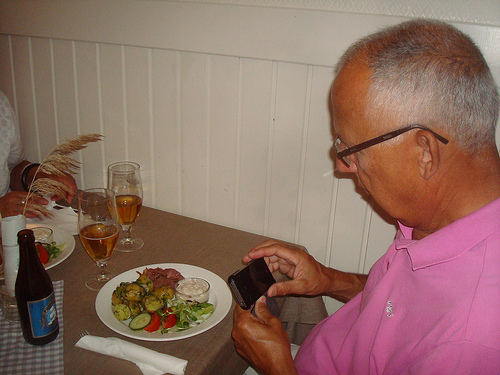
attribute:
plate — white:
[78, 255, 238, 345]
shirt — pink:
[290, 196, 498, 374]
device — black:
[226, 259, 278, 306]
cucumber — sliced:
[127, 312, 162, 329]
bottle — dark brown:
[14, 229, 60, 347]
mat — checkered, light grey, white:
[2, 276, 65, 373]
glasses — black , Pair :
[318, 130, 472, 202]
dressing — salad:
[175, 275, 212, 303]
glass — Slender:
[83, 185, 123, 291]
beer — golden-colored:
[77, 221, 119, 259]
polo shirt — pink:
[291, 195, 497, 372]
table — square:
[69, 173, 293, 374]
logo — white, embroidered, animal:
[384, 304, 395, 321]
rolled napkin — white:
[60, 338, 194, 373]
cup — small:
[172, 274, 212, 301]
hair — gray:
[331, 18, 499, 159]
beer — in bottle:
[13, 227, 61, 346]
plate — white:
[96, 261, 233, 343]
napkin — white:
[79, 335, 184, 374]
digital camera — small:
[229, 243, 276, 304]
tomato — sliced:
[159, 309, 175, 329]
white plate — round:
[73, 269, 233, 333]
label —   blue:
[29, 291, 71, 338]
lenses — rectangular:
[326, 135, 358, 172]